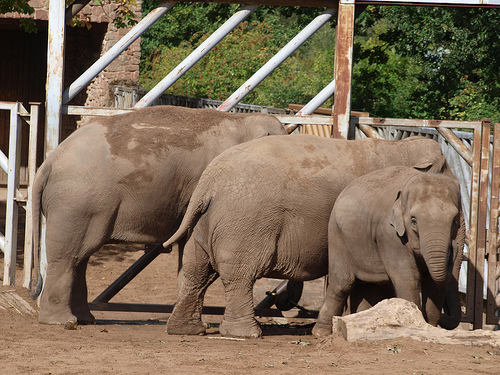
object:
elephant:
[310, 164, 464, 338]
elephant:
[30, 105, 303, 325]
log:
[330, 297, 500, 347]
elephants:
[162, 136, 468, 339]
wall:
[0, 0, 141, 130]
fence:
[0, 100, 56, 306]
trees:
[133, 15, 340, 108]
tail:
[30, 160, 53, 301]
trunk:
[417, 220, 452, 288]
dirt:
[93, 105, 282, 192]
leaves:
[377, 63, 385, 72]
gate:
[484, 119, 500, 324]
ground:
[0, 184, 500, 374]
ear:
[388, 188, 408, 237]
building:
[0, 0, 143, 187]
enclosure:
[0, 0, 500, 375]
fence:
[347, 116, 479, 334]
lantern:
[107, 0, 146, 33]